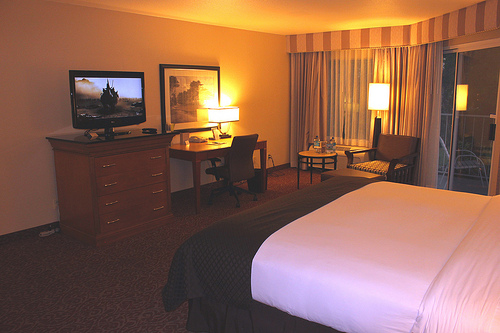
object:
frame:
[159, 63, 223, 136]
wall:
[4, 1, 285, 248]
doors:
[426, 48, 498, 191]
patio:
[433, 124, 498, 190]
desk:
[172, 135, 270, 215]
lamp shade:
[366, 82, 389, 111]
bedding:
[163, 177, 498, 330]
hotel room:
[6, 8, 498, 322]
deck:
[439, 121, 499, 190]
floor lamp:
[367, 83, 390, 161]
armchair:
[344, 117, 419, 183]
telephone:
[189, 136, 207, 143]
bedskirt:
[163, 181, 390, 322]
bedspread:
[252, 178, 499, 331]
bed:
[159, 173, 499, 329]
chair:
[204, 133, 261, 207]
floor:
[0, 153, 342, 330]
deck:
[298, 151, 338, 188]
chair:
[436, 136, 490, 188]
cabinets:
[44, 129, 182, 250]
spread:
[239, 171, 463, 326]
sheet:
[159, 173, 376, 327]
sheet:
[252, 180, 498, 331]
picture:
[161, 64, 222, 135]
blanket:
[415, 192, 500, 332]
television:
[70, 68, 146, 135]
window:
[285, 47, 498, 185]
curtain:
[288, 41, 438, 181]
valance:
[288, 0, 499, 52]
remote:
[142, 125, 158, 135]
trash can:
[246, 168, 269, 193]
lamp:
[209, 109, 242, 140]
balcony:
[440, 112, 490, 192]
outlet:
[54, 196, 59, 208]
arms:
[204, 153, 228, 199]